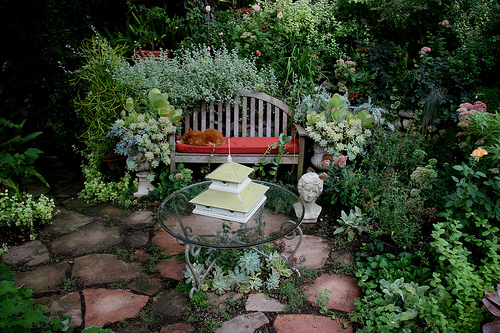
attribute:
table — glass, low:
[156, 178, 303, 303]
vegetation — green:
[436, 100, 498, 280]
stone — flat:
[68, 251, 153, 287]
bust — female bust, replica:
[289, 172, 326, 222]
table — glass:
[157, 178, 315, 294]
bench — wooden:
[162, 82, 309, 193]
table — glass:
[156, 179, 305, 248]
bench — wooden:
[167, 84, 312, 178]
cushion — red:
[172, 120, 297, 150]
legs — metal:
[170, 196, 304, 286]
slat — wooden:
[232, 91, 251, 138]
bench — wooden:
[173, 85, 303, 189]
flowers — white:
[306, 119, 372, 167]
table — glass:
[158, 180, 305, 292]